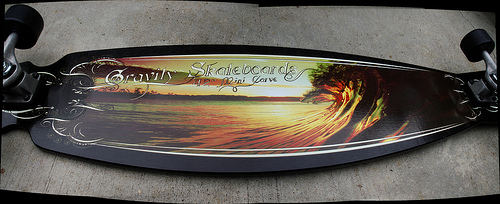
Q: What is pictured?
A: A skateboard.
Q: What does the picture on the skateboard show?
A: A beach wave.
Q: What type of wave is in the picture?
A: A cresting wave.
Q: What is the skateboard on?
A: A gray surface.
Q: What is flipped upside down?
A: A skateboard.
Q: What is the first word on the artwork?
A: Gravity.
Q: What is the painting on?
A: Skateboard.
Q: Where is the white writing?
A: Skateboard.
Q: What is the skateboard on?
A: Cement.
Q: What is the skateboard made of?
A: Wood.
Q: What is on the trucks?
A: Wheels.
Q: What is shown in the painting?
A: Wave.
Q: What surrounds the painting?
A: White line.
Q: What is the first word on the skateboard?
A: Gravity.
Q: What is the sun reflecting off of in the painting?
A: Water.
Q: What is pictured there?
A: Skateboard.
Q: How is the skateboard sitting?
A: Flipped.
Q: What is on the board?
A: Artwork.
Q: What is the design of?
A: Ocean.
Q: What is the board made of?
A: Wood.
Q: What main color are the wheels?
A: Black.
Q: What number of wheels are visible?
A: 2.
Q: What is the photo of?
A: A skateboard.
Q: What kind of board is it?
A: Skateboard.